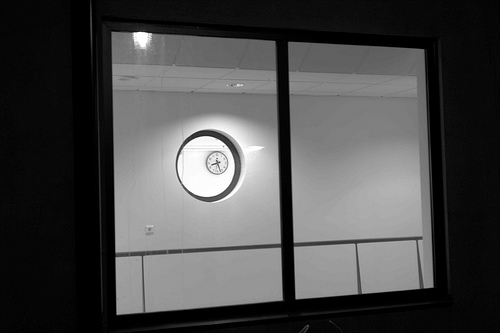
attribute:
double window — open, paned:
[104, 11, 463, 331]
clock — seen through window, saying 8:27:
[148, 118, 263, 204]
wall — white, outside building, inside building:
[331, 127, 368, 169]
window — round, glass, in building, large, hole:
[173, 131, 194, 202]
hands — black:
[214, 165, 228, 171]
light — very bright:
[126, 33, 166, 59]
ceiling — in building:
[202, 44, 245, 60]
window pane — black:
[324, 58, 384, 77]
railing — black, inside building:
[318, 229, 399, 251]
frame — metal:
[85, 14, 129, 53]